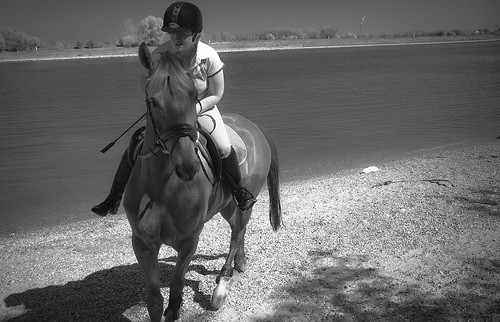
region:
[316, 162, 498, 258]
pebbles along the beach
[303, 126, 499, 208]
a rocky shore line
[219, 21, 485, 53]
a low coast line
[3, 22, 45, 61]
small trees in the distance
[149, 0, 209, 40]
a black riding helmet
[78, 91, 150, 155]
a short dark crop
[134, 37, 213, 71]
a pair of alert ears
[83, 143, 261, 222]
a pair of tall boots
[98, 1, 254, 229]
a young girl riding a horse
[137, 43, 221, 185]
a leather bridle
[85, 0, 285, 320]
girl on race horse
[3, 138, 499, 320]
girl on the shore of the river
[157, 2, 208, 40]
girl wearing black riding helmet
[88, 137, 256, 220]
girl wearing black riding boots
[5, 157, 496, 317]
shore is lighter then the water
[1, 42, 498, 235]
water behind the horse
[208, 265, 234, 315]
horse is white near the hoof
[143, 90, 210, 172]
horse is wearing a bridle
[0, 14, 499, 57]
trees line the far shore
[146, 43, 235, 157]
rider wearing white shirt and pants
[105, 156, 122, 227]
the boots are black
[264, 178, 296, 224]
the tail is black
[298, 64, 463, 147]
the water is calm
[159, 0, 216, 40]
the helmet is black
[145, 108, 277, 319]
the horse is brown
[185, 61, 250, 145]
the pants are white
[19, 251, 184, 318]
the shadow is black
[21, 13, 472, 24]
the sky is dull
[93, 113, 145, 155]
the stick is black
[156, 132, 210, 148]
the rope is black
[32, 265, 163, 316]
shadow of horse in sand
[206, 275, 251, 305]
white part of horse's hoof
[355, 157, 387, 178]
white rock on edge of sand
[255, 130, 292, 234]
long black horse's tail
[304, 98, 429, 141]
calm grey waters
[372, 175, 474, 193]
long branch in sand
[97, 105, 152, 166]
long thin black riding crop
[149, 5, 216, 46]
black cap on woman's head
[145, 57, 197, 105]
blond hair on horse's head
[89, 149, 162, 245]
black riding boot on woman's foot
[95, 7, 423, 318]
horseback riding on beach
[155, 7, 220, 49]
horseback rider's riding helmet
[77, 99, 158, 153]
riding crop while horseback riding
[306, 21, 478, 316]
beach with water in the background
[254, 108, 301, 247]
the mane of a horse on beach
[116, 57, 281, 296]
horse on a beach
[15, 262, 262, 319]
shadow of a horse on a beach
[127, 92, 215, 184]
tack gear worn by horse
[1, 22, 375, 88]
trees in beach background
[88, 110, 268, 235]
riding boots worn by a rider